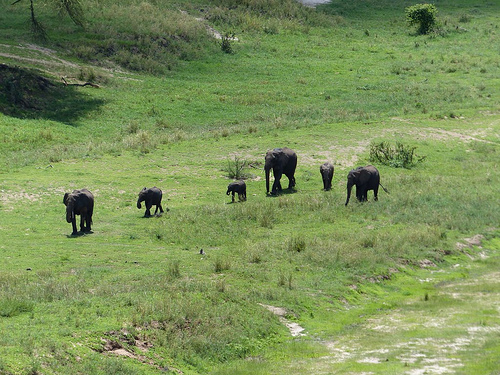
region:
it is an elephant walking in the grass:
[60, 188, 100, 234]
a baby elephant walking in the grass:
[136, 183, 167, 215]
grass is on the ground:
[29, 240, 229, 372]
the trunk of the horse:
[341, 178, 356, 206]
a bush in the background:
[404, 2, 444, 37]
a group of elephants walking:
[51, 143, 401, 250]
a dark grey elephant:
[63, 187, 102, 232]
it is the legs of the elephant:
[271, 170, 298, 191]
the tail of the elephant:
[382, 185, 392, 194]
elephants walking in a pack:
[41, 139, 386, 244]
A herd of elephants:
[63, 151, 389, 238]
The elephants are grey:
[62, 146, 389, 238]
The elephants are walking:
[63, 148, 391, 238]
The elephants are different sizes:
[61, 147, 391, 235]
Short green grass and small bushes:
[4, 5, 484, 362]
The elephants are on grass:
[63, 147, 390, 236]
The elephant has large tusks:
[58, 190, 80, 223]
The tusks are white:
[58, 194, 80, 224]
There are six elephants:
[56, 145, 393, 237]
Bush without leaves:
[219, 149, 259, 184]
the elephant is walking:
[52, 170, 129, 252]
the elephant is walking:
[206, 168, 262, 223]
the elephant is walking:
[254, 128, 306, 219]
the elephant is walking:
[305, 155, 345, 185]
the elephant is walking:
[340, 140, 404, 234]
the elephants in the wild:
[46, 89, 418, 281]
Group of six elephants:
[54, 145, 398, 239]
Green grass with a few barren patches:
[6, 2, 490, 368]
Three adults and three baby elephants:
[57, 147, 389, 236]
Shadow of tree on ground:
[4, 54, 111, 133]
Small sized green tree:
[401, 1, 455, 41]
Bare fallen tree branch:
[4, 58, 99, 89]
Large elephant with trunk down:
[259, 142, 301, 197]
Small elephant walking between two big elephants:
[256, 144, 394, 208]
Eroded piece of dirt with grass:
[78, 317, 192, 374]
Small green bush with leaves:
[360, 134, 429, 171]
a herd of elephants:
[42, 143, 393, 233]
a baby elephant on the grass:
[221, 175, 248, 203]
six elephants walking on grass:
[56, 144, 393, 226]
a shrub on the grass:
[364, 138, 420, 171]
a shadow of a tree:
[1, 64, 117, 129]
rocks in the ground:
[444, 231, 485, 256]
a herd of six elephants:
[57, 148, 392, 238]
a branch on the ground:
[3, 56, 102, 105]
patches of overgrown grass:
[28, 229, 437, 346]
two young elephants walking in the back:
[209, 164, 339, 201]